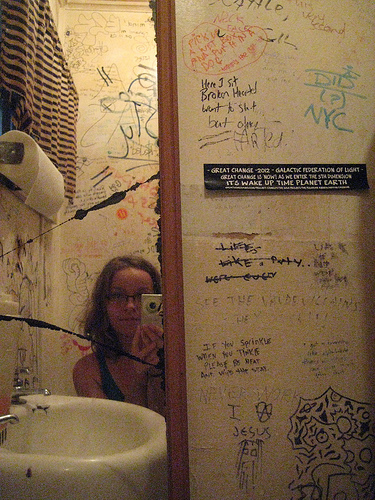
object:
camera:
[140, 292, 165, 348]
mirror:
[0, 0, 175, 499]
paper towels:
[2, 125, 67, 223]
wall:
[1, 1, 165, 405]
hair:
[84, 254, 159, 362]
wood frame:
[146, 2, 192, 499]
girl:
[72, 252, 167, 421]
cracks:
[1, 171, 158, 263]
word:
[201, 78, 217, 89]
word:
[301, 102, 353, 132]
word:
[271, 254, 302, 269]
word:
[311, 240, 333, 251]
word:
[226, 293, 252, 306]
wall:
[171, 0, 375, 499]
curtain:
[0, 0, 82, 207]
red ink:
[180, 11, 268, 77]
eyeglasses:
[102, 289, 144, 304]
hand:
[128, 329, 159, 383]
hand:
[139, 323, 167, 354]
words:
[207, 115, 233, 129]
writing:
[227, 401, 273, 498]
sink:
[1, 392, 170, 497]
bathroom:
[0, 0, 375, 499]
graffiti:
[181, 0, 369, 158]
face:
[107, 267, 155, 337]